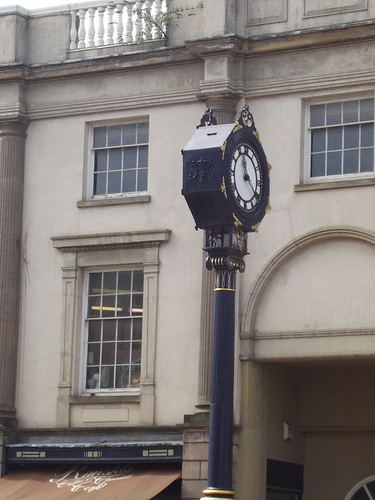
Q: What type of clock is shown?
A: Analog.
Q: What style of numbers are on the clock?
A: Roman.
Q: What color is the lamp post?
A: Blue.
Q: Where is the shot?
A: Street.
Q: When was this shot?
A: Daytime.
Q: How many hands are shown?
A: 2.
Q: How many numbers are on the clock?
A: 12.